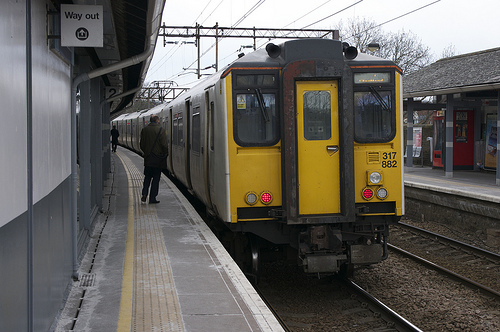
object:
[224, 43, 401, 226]
back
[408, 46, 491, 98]
horse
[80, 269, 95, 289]
metal grating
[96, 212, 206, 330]
train platform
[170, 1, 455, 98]
power lines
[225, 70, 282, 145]
back window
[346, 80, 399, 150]
back window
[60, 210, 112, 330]
drain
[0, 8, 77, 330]
wall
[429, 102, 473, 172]
vending machine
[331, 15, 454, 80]
trees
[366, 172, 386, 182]
rear light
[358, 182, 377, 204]
rear light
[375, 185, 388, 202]
rear light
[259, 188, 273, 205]
rear light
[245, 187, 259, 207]
rear light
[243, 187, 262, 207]
headlight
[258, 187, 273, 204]
headlight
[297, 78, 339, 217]
metal door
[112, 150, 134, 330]
line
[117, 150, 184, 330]
path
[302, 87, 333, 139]
window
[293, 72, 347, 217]
door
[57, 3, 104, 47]
sign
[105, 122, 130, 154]
person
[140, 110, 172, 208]
man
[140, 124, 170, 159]
coat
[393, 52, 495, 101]
roof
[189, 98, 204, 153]
window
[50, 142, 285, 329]
platform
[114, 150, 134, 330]
stripe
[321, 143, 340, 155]
latch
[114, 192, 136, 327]
line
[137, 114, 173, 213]
man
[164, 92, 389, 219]
train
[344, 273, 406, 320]
train tracks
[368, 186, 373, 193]
headlight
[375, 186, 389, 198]
headlight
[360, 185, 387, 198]
pair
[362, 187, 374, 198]
light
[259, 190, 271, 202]
light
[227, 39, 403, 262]
rear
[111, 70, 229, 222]
side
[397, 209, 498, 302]
tracks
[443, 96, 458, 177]
support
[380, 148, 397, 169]
number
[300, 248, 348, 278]
stair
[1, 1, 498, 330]
station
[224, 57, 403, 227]
front